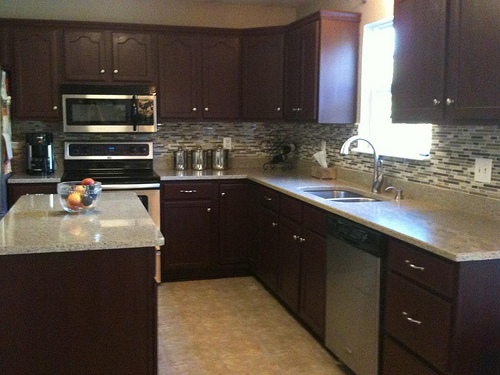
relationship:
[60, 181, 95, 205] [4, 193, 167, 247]
bowl of fruit on counter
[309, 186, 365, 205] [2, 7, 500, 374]
sink in kitchen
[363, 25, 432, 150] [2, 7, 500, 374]
window in kitchen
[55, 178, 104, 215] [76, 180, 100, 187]
fruit bowl full of fruit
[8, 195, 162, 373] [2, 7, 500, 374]
an island in kitchen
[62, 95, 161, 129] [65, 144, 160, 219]
microwave above stove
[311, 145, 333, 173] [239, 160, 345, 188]
box of kleenex on counter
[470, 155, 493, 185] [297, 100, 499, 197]
light switch on wall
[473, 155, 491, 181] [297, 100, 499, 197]
light switch on wall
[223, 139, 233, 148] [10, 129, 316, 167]
power outlet on wall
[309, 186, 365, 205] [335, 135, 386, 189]
sink with tall and curved faucet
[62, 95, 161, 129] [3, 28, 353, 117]
black microwave under dark cabinets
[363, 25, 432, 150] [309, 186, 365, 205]
window above sink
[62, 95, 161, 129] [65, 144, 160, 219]
microwave mounted above stove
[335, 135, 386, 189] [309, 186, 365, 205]
faucet in sink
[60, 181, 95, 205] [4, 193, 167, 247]
fruit bowl on counter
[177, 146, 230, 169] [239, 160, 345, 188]
metal canisters on counter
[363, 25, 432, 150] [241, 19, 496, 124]
window between cupboards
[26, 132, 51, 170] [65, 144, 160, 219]
coffee maker next to stove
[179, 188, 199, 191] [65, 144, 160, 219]
drawer handle to right of stove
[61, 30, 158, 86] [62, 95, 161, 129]
cupboard doors above microwave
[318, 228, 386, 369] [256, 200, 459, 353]
dishwasher built into cupboard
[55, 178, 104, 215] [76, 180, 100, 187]
fruit bowl of fruit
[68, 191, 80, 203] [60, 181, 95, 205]
orange in bowl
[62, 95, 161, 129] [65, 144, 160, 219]
microwave over stove